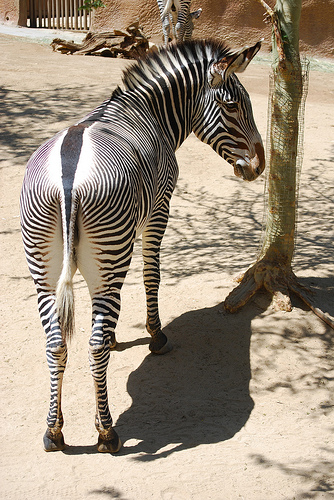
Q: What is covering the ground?
A: Dirt.